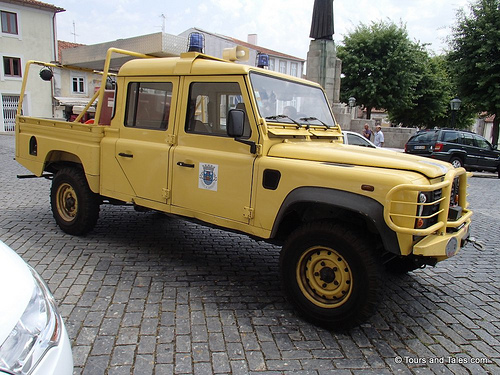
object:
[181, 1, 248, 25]
clouds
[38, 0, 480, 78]
sky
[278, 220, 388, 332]
tire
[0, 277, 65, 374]
headlight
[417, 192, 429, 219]
headlight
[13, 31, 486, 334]
car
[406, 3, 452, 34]
clouds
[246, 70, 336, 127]
windshield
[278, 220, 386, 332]
sheel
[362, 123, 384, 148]
people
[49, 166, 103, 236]
rear wheel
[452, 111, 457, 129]
post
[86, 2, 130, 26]
clouds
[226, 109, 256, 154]
side mirror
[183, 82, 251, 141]
window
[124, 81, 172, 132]
window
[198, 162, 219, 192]
decal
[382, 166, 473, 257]
bumper guard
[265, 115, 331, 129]
wipers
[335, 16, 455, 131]
trees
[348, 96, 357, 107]
lights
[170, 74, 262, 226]
door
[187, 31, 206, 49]
blue light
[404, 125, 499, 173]
black suv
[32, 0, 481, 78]
blue sky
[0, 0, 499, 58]
background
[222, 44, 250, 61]
speaker system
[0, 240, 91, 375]
car